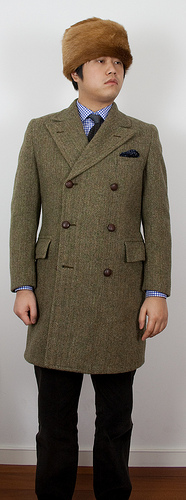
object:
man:
[10, 17, 171, 499]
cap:
[63, 17, 132, 78]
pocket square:
[119, 157, 141, 194]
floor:
[0, 462, 186, 499]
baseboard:
[0, 449, 186, 467]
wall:
[0, 0, 186, 448]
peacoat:
[10, 101, 171, 370]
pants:
[34, 368, 133, 499]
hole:
[62, 264, 74, 268]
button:
[103, 268, 112, 276]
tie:
[88, 114, 105, 142]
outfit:
[8, 101, 171, 500]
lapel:
[44, 100, 88, 169]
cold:
[9, 101, 171, 373]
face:
[83, 57, 124, 96]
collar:
[77, 101, 92, 122]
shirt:
[76, 102, 112, 136]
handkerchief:
[120, 149, 139, 158]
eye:
[97, 60, 104, 63]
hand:
[138, 297, 168, 341]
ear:
[71, 72, 79, 82]